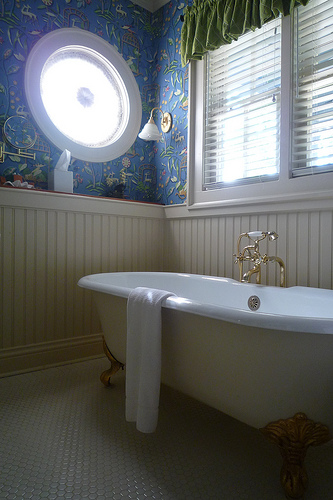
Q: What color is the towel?
A: White.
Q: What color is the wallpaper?
A: Blue.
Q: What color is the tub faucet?
A: Gold.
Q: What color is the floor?
A: Tan.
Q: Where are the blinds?
A: Over the window.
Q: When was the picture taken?
A: During the day.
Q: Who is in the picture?
A: There are no people in the image.